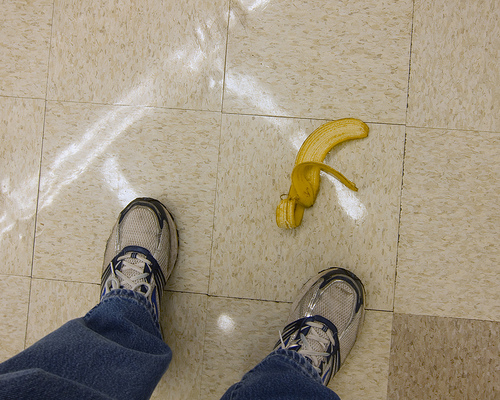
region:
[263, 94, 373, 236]
a banana on the floor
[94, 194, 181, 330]
the left shoe on a person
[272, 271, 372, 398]
the right shoe of a person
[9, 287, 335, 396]
blue jeans being worn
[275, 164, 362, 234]
a banana peel lying on the ground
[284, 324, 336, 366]
white tennis shoe laces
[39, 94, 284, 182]
grey and brown colored tile flooring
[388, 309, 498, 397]
a dark brown piece of tile flooring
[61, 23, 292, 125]
the reflection of light off a tile floor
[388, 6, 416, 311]
grout lines on a piece of tile floor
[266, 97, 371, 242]
banana peel on floor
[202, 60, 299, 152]
white light reflectedin floor tiles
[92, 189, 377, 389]
blue and white sneakers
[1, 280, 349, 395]
bottom of blue jeans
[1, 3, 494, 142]
tan tiled flooring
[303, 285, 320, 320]
silver accent on sneakers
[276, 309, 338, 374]
white shoe laces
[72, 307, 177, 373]
wrinkle in blue jeans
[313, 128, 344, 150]
white interior of banana peel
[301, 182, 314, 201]
brown mark on banana peel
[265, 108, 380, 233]
Peel on the ground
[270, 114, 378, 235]
Peel is on the ground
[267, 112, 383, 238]
Peel on the floor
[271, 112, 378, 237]
Peel is on the floor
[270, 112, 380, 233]
Banana peel on the ground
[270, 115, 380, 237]
Banana peel is on the ground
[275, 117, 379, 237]
Banana peel on the floor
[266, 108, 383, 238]
Banana peel is on the floor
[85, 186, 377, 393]
Person wearing white and blue shoes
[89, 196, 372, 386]
Person is wearing white and blue shoes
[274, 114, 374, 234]
one yellow banana peel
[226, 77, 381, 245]
streak on sun near banana peel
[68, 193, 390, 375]
two white and blue sneakers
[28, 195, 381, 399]
bottom of two legs wearing blue jeans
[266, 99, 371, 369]
one foot near banana peel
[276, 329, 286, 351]
one white shoelace aglet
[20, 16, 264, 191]
section of partially sunlit floor tiles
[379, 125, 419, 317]
commercial floor tile seam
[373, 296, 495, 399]
one brown floor tile next to light floor tiles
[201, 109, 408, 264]
banana peel on square shaped floor tile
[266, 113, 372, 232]
banana peel on floor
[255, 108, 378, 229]
banana peel on tile floor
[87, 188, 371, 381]
black and white athletic footwear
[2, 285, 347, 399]
dark blue denim pants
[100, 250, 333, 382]
white shoe laces in footwear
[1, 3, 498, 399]
tile floor with gold colored flecks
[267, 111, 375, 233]
yellow banana peel on floor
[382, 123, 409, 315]
edge between two floor tiles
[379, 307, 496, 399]
floor tile darker than others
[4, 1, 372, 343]
reflection of light on floor tiles